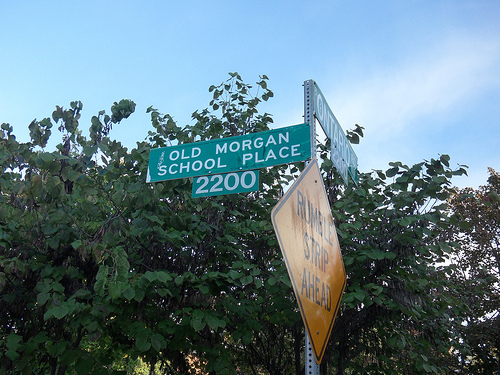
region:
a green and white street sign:
[138, 125, 309, 195]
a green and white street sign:
[306, 83, 389, 180]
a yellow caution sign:
[273, 165, 346, 359]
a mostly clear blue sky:
[8, 5, 487, 90]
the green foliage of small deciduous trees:
[7, 105, 144, 374]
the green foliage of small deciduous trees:
[373, 166, 499, 361]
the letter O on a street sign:
[166, 148, 182, 163]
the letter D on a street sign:
[188, 142, 203, 157]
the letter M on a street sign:
[212, 140, 227, 155]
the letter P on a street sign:
[240, 150, 252, 165]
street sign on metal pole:
[136, 120, 301, 182]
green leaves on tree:
[92, 274, 124, 303]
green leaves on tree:
[229, 298, 260, 330]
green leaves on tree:
[123, 318, 146, 341]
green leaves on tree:
[92, 238, 117, 261]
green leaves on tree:
[366, 290, 390, 315]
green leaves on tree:
[114, 240, 134, 259]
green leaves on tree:
[206, 235, 231, 262]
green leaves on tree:
[47, 208, 74, 232]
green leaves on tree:
[127, 194, 164, 227]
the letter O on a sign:
[166, 148, 180, 160]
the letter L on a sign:
[176, 146, 191, 158]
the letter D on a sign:
[190, 143, 200, 158]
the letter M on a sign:
[211, 140, 228, 155]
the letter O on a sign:
[228, 140, 242, 152]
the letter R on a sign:
[240, 138, 251, 152]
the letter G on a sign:
[252, 135, 263, 150]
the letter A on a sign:
[263, 131, 275, 147]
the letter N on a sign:
[276, 130, 293, 143]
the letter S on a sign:
[156, 162, 167, 177]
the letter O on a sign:
[168, 147, 178, 161]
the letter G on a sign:
[250, 134, 267, 148]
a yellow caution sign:
[270, 158, 353, 361]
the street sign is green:
[119, 119, 326, 227]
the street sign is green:
[112, 111, 313, 203]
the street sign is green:
[118, 121, 313, 218]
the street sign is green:
[107, 119, 334, 220]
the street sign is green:
[122, 113, 319, 210]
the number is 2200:
[180, 170, 272, 208]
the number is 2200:
[190, 170, 285, 212]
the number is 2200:
[176, 164, 262, 206]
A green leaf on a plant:
[108, 279, 122, 298]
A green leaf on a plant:
[144, 269, 153, 282]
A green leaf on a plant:
[154, 271, 171, 283]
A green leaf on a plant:
[119, 102, 129, 108]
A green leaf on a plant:
[103, 112, 108, 122]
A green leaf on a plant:
[64, 110, 71, 115]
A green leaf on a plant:
[37, 153, 51, 162]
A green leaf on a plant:
[397, 192, 408, 197]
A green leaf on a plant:
[395, 175, 404, 179]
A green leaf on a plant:
[432, 175, 444, 183]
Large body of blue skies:
[377, 19, 477, 114]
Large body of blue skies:
[364, 25, 451, 126]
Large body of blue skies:
[399, 5, 487, 120]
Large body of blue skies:
[4, 4, 131, 84]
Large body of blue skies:
[401, 23, 497, 128]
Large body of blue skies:
[375, 10, 475, 109]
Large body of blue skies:
[392, 30, 499, 145]